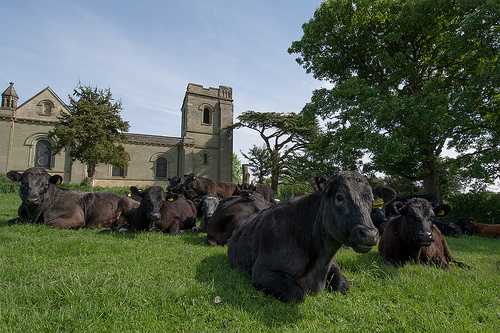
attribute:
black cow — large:
[226, 171, 396, 306]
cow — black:
[231, 167, 396, 309]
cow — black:
[373, 192, 475, 273]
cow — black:
[455, 216, 478, 234]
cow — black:
[7, 163, 138, 229]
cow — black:
[116, 178, 201, 237]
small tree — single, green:
[46, 74, 131, 186]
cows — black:
[9, 165, 466, 305]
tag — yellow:
[167, 193, 175, 203]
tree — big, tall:
[275, 86, 498, 206]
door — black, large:
[19, 137, 58, 182]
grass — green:
[6, 231, 497, 331]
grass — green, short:
[0, 191, 497, 331]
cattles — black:
[6, 145, 482, 302]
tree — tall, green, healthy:
[278, 7, 499, 227]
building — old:
[1, 79, 233, 189]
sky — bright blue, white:
[90, 3, 207, 51]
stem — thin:
[219, 114, 258, 132]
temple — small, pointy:
[2, 78, 17, 116]